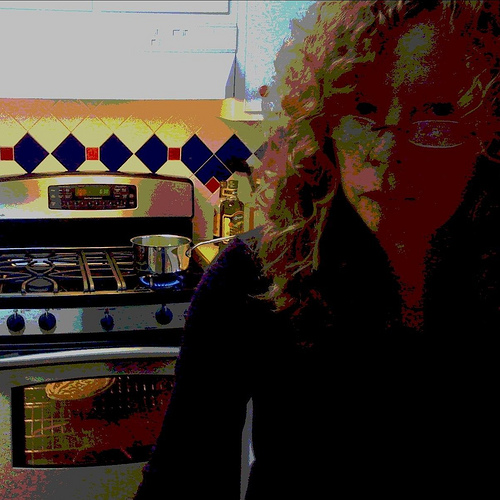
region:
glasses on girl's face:
[306, 69, 486, 167]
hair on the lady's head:
[222, 33, 371, 245]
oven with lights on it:
[41, 168, 144, 220]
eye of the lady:
[339, 88, 394, 125]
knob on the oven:
[76, 296, 132, 341]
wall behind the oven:
[28, 107, 170, 159]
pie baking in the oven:
[43, 373, 115, 404]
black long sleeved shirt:
[131, 185, 498, 498]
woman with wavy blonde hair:
[133, 0, 498, 499]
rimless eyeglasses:
[316, 113, 487, 148]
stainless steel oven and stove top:
[1, 170, 211, 497]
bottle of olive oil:
[218, 178, 243, 249]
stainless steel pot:
[127, 232, 239, 276]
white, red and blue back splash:
[0, 98, 264, 246]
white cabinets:
[0, 0, 317, 122]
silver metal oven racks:
[24, 375, 174, 455]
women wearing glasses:
[336, 110, 459, 157]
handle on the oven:
[68, 346, 133, 356]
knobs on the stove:
[31, 312, 56, 334]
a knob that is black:
[98, 314, 118, 332]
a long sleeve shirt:
[196, 325, 250, 376]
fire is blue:
[148, 276, 174, 290]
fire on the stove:
[155, 277, 175, 287]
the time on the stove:
[94, 183, 121, 197]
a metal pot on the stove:
[128, 221, 240, 278]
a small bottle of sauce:
[211, 171, 245, 246]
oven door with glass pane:
[0, 348, 157, 483]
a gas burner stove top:
[4, 230, 201, 297]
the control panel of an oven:
[4, 171, 191, 219]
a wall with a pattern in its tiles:
[1, 110, 258, 191]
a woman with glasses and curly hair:
[192, 4, 497, 498]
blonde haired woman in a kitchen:
[148, 5, 495, 497]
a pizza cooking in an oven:
[32, 377, 139, 449]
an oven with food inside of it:
[4, 174, 215, 491]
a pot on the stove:
[128, 217, 191, 277]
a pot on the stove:
[120, 212, 223, 313]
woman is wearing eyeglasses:
[306, 40, 445, 300]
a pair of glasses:
[313, 100, 468, 163]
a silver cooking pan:
[123, 218, 231, 278]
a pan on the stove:
[120, 220, 198, 315]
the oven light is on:
[0, 374, 149, 481]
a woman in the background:
[241, 3, 496, 311]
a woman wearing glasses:
[248, 6, 498, 306]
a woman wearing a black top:
[164, 13, 494, 470]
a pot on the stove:
[118, 175, 240, 305]